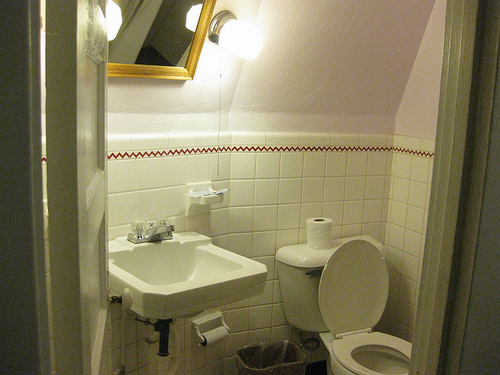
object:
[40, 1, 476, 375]
bathroom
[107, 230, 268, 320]
sink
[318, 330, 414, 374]
toilet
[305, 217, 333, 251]
toilet paper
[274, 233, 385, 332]
tank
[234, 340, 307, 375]
garbage can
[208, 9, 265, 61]
light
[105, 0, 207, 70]
mirror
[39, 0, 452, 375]
wall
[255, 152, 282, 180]
tile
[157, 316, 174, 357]
pipe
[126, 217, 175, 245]
faucet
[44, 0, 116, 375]
door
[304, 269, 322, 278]
handle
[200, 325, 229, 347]
roll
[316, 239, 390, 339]
lid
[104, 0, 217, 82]
frame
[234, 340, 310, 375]
bag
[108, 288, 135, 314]
doorknob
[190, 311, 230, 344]
holder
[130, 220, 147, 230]
fixtures